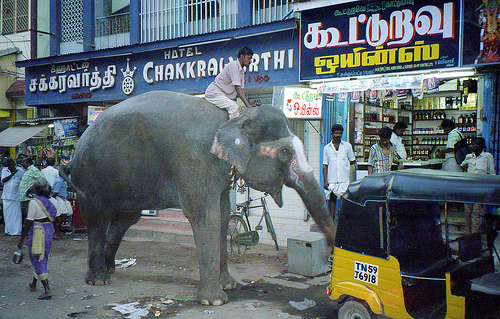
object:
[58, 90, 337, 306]
elepahant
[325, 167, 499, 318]
car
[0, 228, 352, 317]
street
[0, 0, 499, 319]
building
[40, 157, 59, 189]
person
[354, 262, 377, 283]
black letters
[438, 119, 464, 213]
person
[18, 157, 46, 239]
person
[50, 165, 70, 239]
person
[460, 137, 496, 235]
person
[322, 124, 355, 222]
person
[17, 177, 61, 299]
person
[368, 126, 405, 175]
person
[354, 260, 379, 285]
sign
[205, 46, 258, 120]
man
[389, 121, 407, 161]
person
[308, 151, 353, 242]
standing up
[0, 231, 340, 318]
road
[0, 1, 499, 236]
wall